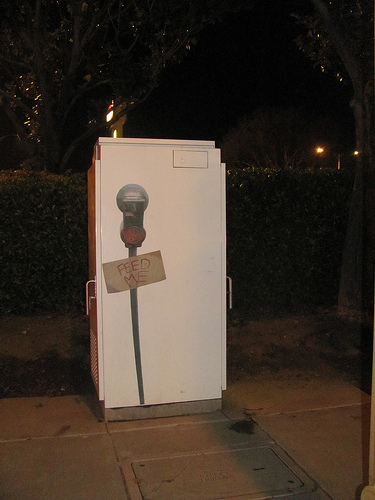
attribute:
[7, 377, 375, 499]
path — gray, cement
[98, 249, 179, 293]
poster — painted, brown, cardboard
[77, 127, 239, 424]
structure — white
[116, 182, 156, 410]
parking meter — painted, gray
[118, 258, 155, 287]
writing — red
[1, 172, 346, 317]
hedge — green, tall, trimmed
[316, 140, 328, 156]
light — yellow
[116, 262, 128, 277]
letter "f" — red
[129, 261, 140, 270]
letter "e" — red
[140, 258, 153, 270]
letter "d" — red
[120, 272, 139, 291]
letter "m" — red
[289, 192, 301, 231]
leaves — green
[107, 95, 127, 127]
sign — lit